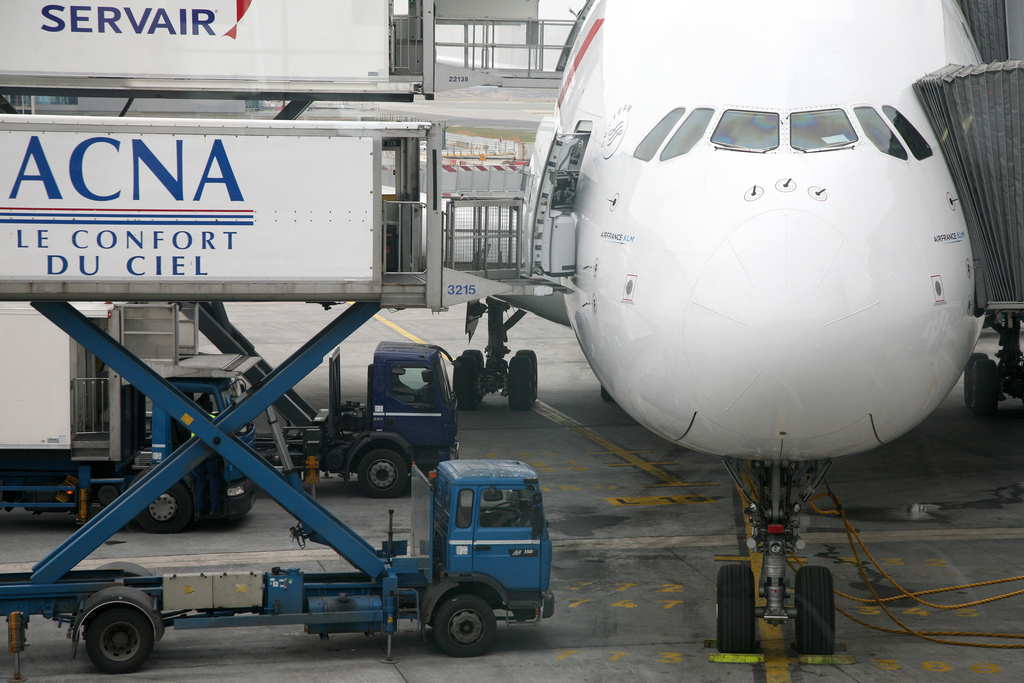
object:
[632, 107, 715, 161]
window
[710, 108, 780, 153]
window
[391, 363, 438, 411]
window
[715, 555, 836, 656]
wheels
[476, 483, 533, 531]
window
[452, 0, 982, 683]
plane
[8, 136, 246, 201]
acna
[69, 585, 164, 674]
wheels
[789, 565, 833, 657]
wheel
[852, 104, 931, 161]
window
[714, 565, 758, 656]
wheel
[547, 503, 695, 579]
water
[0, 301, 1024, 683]
cement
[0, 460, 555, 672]
truck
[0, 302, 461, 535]
truck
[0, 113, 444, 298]
trailer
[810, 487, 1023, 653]
cord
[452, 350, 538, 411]
wheels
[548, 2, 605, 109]
stripe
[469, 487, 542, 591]
door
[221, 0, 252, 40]
part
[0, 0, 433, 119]
truck